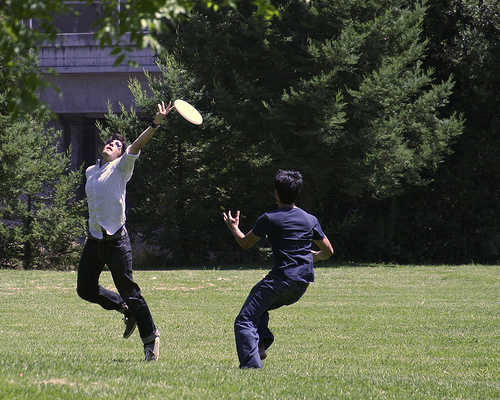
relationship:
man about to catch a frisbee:
[67, 104, 165, 361] [171, 96, 205, 128]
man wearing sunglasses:
[67, 104, 165, 361] [102, 135, 126, 149]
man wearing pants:
[67, 104, 165, 361] [70, 225, 162, 342]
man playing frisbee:
[67, 104, 165, 361] [171, 96, 205, 128]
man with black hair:
[219, 162, 336, 373] [273, 168, 304, 209]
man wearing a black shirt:
[219, 162, 336, 373] [247, 205, 325, 285]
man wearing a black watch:
[67, 104, 165, 361] [147, 117, 161, 131]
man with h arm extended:
[67, 104, 165, 361] [126, 98, 176, 171]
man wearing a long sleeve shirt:
[67, 104, 165, 361] [78, 146, 141, 238]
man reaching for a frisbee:
[67, 104, 165, 361] [171, 96, 205, 128]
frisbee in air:
[171, 96, 205, 128] [175, 58, 229, 96]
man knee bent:
[67, 104, 165, 361] [66, 274, 108, 305]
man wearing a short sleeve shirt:
[219, 162, 336, 373] [247, 205, 325, 285]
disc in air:
[171, 96, 205, 128] [175, 58, 229, 96]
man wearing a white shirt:
[67, 104, 165, 361] [78, 146, 141, 238]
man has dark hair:
[219, 162, 336, 373] [273, 168, 304, 209]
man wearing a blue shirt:
[219, 162, 336, 373] [247, 205, 325, 285]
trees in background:
[187, 7, 426, 118] [425, 9, 488, 137]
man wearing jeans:
[219, 162, 336, 373] [233, 264, 310, 357]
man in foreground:
[219, 162, 336, 373] [196, 267, 197, 268]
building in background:
[6, 0, 186, 134] [425, 9, 488, 137]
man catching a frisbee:
[67, 104, 165, 361] [171, 96, 205, 128]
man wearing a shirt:
[67, 104, 165, 361] [78, 146, 141, 238]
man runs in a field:
[219, 162, 336, 373] [171, 247, 231, 380]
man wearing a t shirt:
[219, 162, 336, 373] [247, 205, 325, 285]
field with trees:
[171, 247, 231, 380] [187, 7, 426, 118]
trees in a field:
[187, 7, 426, 118] [171, 247, 231, 380]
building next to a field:
[6, 0, 186, 134] [171, 247, 231, 380]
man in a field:
[219, 162, 336, 373] [171, 247, 231, 380]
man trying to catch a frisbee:
[67, 104, 165, 361] [171, 96, 205, 128]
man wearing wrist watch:
[67, 104, 165, 361] [149, 119, 163, 129]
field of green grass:
[171, 247, 231, 380] [352, 265, 397, 363]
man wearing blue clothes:
[219, 162, 336, 373] [257, 202, 293, 360]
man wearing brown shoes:
[67, 104, 165, 361] [114, 305, 162, 362]